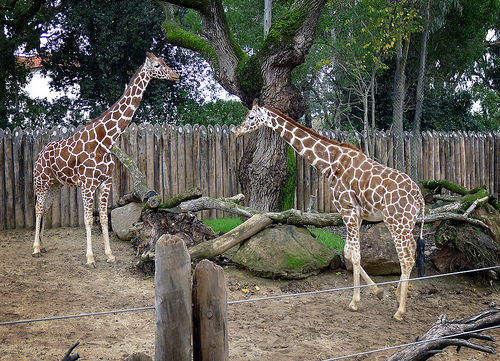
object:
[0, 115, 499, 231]
fence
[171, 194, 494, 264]
log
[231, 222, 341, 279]
rock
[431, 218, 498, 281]
rock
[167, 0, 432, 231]
tree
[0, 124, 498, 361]
enclosure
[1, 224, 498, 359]
sand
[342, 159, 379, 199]
fur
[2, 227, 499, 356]
ground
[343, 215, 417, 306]
leg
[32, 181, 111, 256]
leg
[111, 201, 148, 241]
rock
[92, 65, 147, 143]
neck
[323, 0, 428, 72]
leaves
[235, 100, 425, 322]
giraffe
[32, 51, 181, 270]
giraffe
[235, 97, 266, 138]
head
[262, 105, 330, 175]
neck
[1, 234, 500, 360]
fence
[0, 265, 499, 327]
wire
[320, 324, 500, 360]
wire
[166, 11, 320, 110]
moss